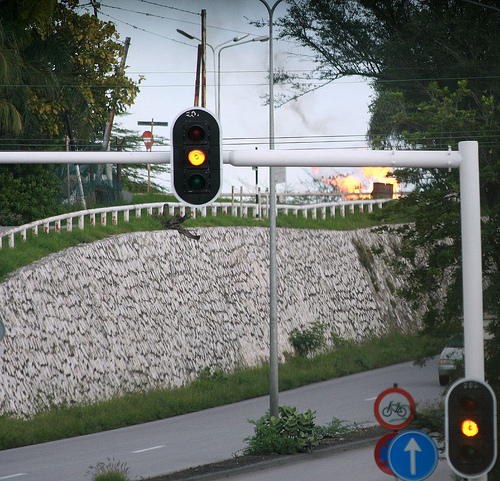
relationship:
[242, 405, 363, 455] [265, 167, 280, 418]
bush by the pole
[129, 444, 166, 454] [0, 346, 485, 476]
lines on road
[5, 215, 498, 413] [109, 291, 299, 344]
wall has rock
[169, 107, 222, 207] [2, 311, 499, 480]
light on road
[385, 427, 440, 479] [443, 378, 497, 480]
sign next to stop light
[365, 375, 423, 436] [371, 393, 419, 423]
sign with bicycle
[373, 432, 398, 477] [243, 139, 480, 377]
sign on post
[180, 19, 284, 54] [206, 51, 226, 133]
street lights on pole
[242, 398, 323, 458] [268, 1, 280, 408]
bush near pole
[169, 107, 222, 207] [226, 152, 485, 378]
light on post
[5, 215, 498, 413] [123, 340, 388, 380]
wall by grass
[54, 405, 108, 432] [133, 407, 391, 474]
grass on road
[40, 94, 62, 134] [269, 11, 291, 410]
flowers around pole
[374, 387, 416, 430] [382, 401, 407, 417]
sign has bicycle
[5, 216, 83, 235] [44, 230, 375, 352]
fence on top of brick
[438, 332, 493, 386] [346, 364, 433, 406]
car in road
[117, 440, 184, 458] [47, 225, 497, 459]
lines in road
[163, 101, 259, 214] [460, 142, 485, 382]
light on pole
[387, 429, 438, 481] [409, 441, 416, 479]
sign with arrow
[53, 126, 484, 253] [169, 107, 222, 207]
pole with light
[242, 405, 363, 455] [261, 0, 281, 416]
bush by gray pole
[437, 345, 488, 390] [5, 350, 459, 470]
car by road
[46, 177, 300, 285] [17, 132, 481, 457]
guard by road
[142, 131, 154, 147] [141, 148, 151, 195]
sign on pole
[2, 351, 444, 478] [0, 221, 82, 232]
road above road